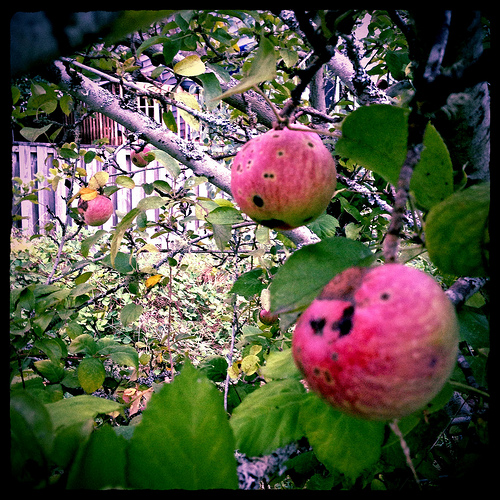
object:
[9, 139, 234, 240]
wooden fence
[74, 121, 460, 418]
apples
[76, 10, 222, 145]
house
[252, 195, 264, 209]
hole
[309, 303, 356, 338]
hole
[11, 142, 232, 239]
fence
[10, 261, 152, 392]
leaves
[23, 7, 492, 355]
leaves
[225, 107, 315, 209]
street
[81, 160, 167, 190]
branch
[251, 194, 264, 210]
black holes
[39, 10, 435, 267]
tree branch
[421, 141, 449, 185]
ground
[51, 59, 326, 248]
branch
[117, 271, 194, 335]
vegetation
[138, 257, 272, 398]
ground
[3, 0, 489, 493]
tree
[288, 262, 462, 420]
black dots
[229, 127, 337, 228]
black dots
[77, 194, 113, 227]
black dots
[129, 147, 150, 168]
black dots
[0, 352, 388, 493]
leaf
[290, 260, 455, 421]
pink fruit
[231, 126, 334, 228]
pink fruit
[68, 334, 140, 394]
leaf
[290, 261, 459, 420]
apple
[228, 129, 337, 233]
apple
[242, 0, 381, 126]
branch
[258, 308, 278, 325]
fruit